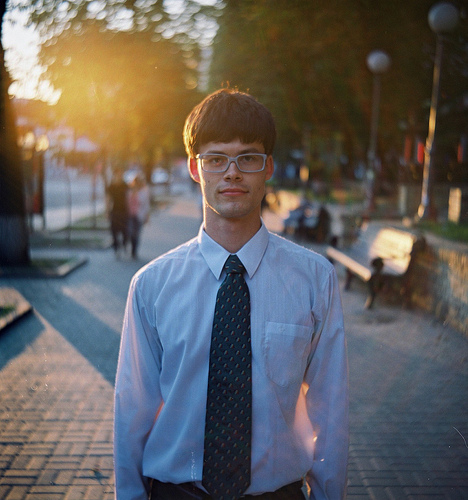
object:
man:
[110, 86, 352, 497]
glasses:
[194, 148, 271, 173]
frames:
[195, 150, 270, 174]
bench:
[325, 221, 426, 311]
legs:
[362, 281, 383, 309]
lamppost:
[419, 33, 446, 203]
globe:
[367, 50, 390, 74]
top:
[370, 44, 387, 51]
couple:
[104, 165, 152, 261]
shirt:
[106, 222, 351, 500]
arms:
[306, 254, 351, 499]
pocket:
[260, 320, 315, 389]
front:
[0, 184, 468, 500]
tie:
[199, 258, 253, 498]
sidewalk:
[30, 248, 102, 257]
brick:
[57, 410, 73, 421]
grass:
[418, 216, 468, 244]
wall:
[398, 240, 464, 330]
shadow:
[6, 262, 121, 390]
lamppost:
[365, 73, 381, 208]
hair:
[181, 87, 278, 159]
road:
[29, 203, 106, 235]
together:
[102, 166, 154, 261]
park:
[0, 117, 468, 500]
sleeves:
[109, 266, 161, 498]